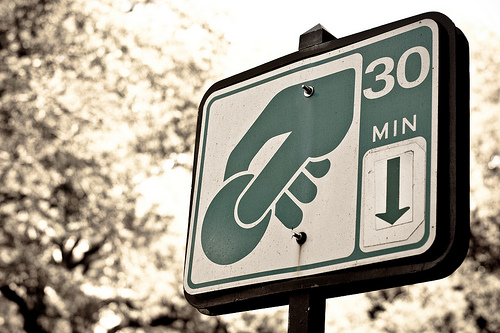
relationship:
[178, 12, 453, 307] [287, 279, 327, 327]
sign on pole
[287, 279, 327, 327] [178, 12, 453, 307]
pole with sign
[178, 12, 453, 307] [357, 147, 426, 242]
sign with arrow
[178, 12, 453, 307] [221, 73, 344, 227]
sign with hand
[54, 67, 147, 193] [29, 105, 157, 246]
tree has flower